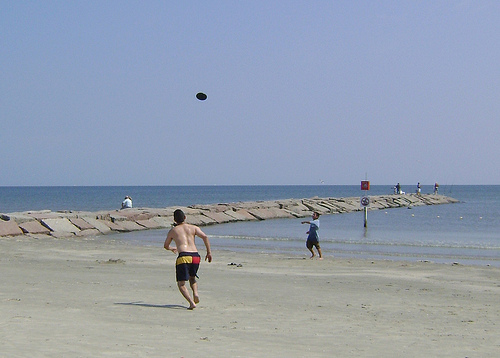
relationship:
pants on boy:
[305, 240, 320, 249] [301, 208, 323, 258]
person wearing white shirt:
[116, 195, 133, 211] [116, 190, 140, 210]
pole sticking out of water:
[355, 170, 382, 247] [9, 169, 483, 268]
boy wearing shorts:
[163, 209, 212, 309] [165, 247, 205, 283]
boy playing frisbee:
[301, 212, 324, 260] [194, 91, 208, 103]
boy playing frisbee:
[163, 209, 212, 309] [194, 91, 208, 103]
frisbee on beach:
[194, 91, 208, 103] [0, 234, 497, 356]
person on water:
[118, 195, 138, 211] [2, 185, 496, 267]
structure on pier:
[167, 186, 315, 228] [123, 187, 360, 224]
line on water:
[377, 207, 499, 222] [8, 177, 495, 245]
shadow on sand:
[107, 294, 203, 324] [24, 253, 257, 356]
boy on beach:
[301, 207, 325, 259] [335, 253, 492, 350]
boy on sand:
[160, 207, 213, 309] [212, 282, 437, 333]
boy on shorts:
[160, 207, 213, 309] [175, 250, 201, 282]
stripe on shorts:
[169, 250, 222, 275] [162, 236, 231, 299]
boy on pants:
[301, 212, 324, 260] [305, 237, 320, 251]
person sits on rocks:
[116, 195, 133, 211] [73, 206, 176, 226]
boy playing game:
[163, 209, 212, 309] [101, 64, 377, 325]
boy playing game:
[301, 212, 324, 260] [101, 64, 377, 325]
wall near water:
[98, 208, 165, 228] [24, 160, 494, 268]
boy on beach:
[301, 212, 324, 260] [5, 178, 495, 351]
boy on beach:
[163, 209, 212, 309] [5, 178, 495, 351]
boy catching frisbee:
[163, 209, 212, 309] [192, 90, 217, 107]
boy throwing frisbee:
[301, 212, 324, 260] [196, 90, 208, 100]